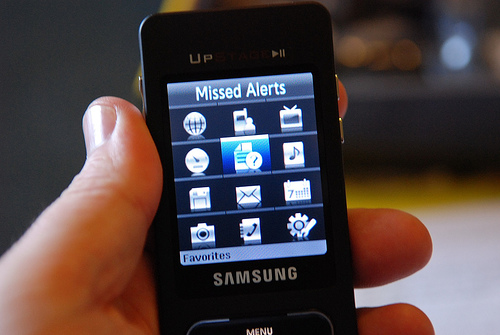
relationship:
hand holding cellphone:
[3, 77, 437, 334] [137, 1, 356, 332]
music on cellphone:
[278, 141, 311, 169] [138, 1, 355, 335]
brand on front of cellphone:
[210, 267, 301, 288] [138, 1, 355, 335]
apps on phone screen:
[178, 101, 328, 244] [165, 76, 328, 267]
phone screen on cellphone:
[165, 76, 328, 267] [138, 1, 355, 335]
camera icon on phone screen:
[180, 220, 221, 244] [170, 76, 350, 286]